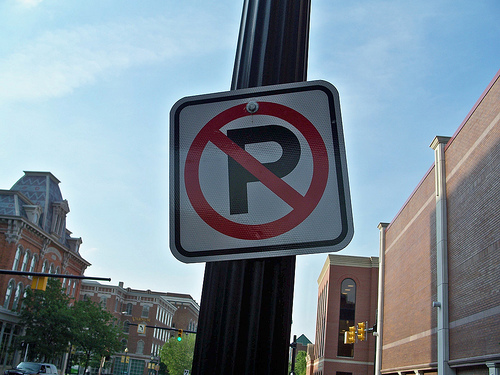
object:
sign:
[170, 80, 355, 264]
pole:
[189, 1, 311, 374]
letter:
[227, 123, 300, 216]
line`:
[211, 130, 304, 209]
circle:
[186, 102, 328, 240]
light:
[348, 323, 354, 343]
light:
[176, 335, 182, 341]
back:
[32, 273, 46, 291]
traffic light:
[30, 276, 48, 292]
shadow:
[429, 135, 497, 375]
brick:
[374, 69, 500, 374]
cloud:
[1, 1, 41, 37]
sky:
[0, 0, 500, 348]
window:
[169, 315, 174, 328]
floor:
[82, 284, 176, 326]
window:
[337, 278, 358, 359]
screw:
[247, 100, 260, 114]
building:
[311, 254, 380, 374]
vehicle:
[9, 361, 60, 374]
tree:
[295, 350, 309, 374]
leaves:
[295, 348, 308, 374]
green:
[178, 335, 183, 340]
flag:
[99, 356, 108, 367]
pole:
[97, 351, 108, 372]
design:
[43, 244, 63, 264]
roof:
[0, 170, 92, 273]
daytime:
[0, 0, 500, 374]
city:
[0, 1, 499, 374]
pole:
[365, 324, 378, 333]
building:
[0, 169, 92, 373]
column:
[428, 136, 449, 374]